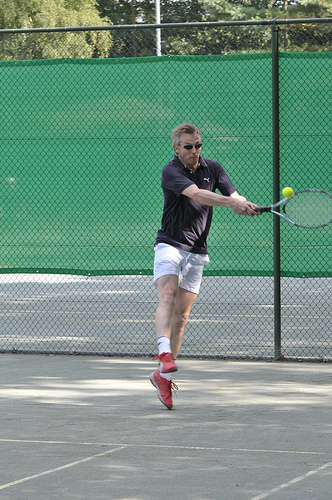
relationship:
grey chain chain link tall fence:
[191, 89, 227, 113] [0, 0, 330, 117]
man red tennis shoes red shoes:
[146, 120, 264, 413] [139, 345, 190, 415]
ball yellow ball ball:
[282, 186, 294, 200] [282, 186, 294, 200]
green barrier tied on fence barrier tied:
[0, 54, 331, 66] [1, 266, 156, 279]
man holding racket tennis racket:
[146, 120, 264, 413] [233, 166, 331, 249]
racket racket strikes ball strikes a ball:
[249, 187, 332, 234] [233, 166, 331, 249]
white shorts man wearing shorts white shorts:
[150, 242, 215, 298] [153, 242, 210, 297]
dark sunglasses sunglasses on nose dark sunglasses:
[175, 143, 203, 150] [175, 143, 203, 150]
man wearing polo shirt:
[146, 120, 264, 413] [166, 168, 227, 187]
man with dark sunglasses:
[146, 120, 264, 413] [176, 143, 209, 151]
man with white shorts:
[146, 120, 264, 413] [150, 242, 215, 298]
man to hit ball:
[146, 120, 264, 413] [278, 183, 294, 196]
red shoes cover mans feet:
[139, 345, 190, 415] [138, 348, 179, 420]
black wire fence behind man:
[0, 17, 332, 363] [146, 120, 264, 413]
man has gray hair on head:
[146, 120, 264, 413] [176, 126, 197, 134]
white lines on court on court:
[0, 445, 128, 489] [8, 342, 129, 486]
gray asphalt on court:
[196, 419, 290, 441] [75, 402, 259, 498]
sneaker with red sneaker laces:
[142, 368, 183, 416] [172, 387, 178, 399]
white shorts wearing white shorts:
[153, 242, 210, 297] [153, 242, 210, 297]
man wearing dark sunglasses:
[146, 120, 264, 413] [175, 143, 203, 150]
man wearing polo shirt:
[145, 159, 225, 250] [153, 154, 237, 255]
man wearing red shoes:
[146, 120, 264, 413] [152, 348, 179, 374]